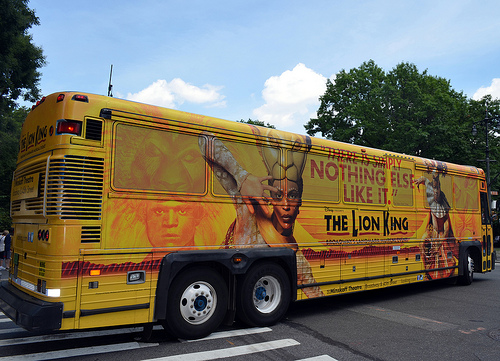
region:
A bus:
[104, 116, 302, 349]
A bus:
[190, 140, 355, 353]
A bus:
[46, 59, 353, 336]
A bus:
[168, 88, 316, 269]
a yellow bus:
[4, 68, 498, 335]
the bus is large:
[5, 87, 497, 347]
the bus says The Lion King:
[299, 197, 452, 264]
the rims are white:
[148, 258, 317, 343]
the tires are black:
[149, 236, 299, 346]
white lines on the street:
[2, 318, 348, 357]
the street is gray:
[281, 272, 498, 351]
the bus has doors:
[468, 174, 498, 281]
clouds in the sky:
[128, 46, 498, 168]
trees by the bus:
[296, 50, 497, 321]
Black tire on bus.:
[172, 259, 275, 359]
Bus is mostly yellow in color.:
[28, 125, 441, 359]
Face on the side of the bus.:
[98, 175, 240, 300]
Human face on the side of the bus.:
[231, 150, 346, 256]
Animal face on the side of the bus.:
[247, 125, 308, 212]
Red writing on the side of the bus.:
[306, 135, 438, 235]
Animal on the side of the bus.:
[411, 165, 478, 262]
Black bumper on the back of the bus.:
[1, 277, 78, 354]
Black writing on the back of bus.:
[11, 125, 96, 168]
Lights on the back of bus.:
[28, 218, 60, 255]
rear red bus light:
[58, 119, 83, 135]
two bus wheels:
[158, 248, 295, 343]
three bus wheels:
[158, 242, 492, 342]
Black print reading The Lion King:
[318, 207, 418, 239]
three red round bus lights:
[33, 229, 51, 244]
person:
[1, 227, 14, 266]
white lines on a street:
[1, 319, 342, 359]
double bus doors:
[477, 190, 496, 272]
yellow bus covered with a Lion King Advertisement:
[13, 91, 496, 341]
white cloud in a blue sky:
[246, 61, 317, 110]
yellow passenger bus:
[8, 63, 496, 348]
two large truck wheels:
[131, 235, 301, 337]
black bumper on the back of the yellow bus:
[1, 265, 92, 331]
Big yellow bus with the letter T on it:
[295, 191, 425, 286]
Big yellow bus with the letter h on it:
[286, 195, 436, 270]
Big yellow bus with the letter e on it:
[295, 200, 421, 270]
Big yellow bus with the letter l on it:
[265, 199, 437, 270]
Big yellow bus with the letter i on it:
[257, 201, 422, 265]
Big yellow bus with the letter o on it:
[315, 210, 431, 257]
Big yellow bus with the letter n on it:
[277, 203, 435, 263]